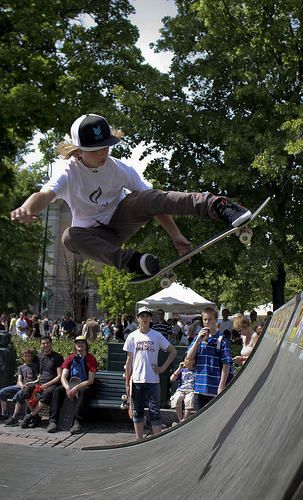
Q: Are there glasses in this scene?
A: No, there are no glasses.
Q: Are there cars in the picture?
A: No, there are no cars.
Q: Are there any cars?
A: No, there are no cars.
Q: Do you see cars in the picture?
A: No, there are no cars.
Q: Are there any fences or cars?
A: No, there are no cars or fences.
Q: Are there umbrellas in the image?
A: No, there are no umbrellas.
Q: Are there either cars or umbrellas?
A: No, there are no umbrellas or cars.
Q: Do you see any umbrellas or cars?
A: No, there are no umbrellas or cars.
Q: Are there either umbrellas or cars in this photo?
A: No, there are no umbrellas or cars.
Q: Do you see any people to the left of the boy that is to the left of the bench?
A: Yes, there are people to the left of the boy.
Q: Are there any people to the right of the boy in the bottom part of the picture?
A: No, the people are to the left of the boy.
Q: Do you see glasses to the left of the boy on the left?
A: No, there are people to the left of the boy.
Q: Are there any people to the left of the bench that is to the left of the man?
A: Yes, there are people to the left of the bench.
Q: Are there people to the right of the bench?
A: No, the people are to the left of the bench.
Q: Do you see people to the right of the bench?
A: No, the people are to the left of the bench.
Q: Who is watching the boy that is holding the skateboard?
A: The people are watching the boy.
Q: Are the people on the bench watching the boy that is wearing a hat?
A: Yes, the people are watching the boy.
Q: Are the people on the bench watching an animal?
A: No, the people are watching the boy.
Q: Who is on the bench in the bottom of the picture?
A: The people are on the bench.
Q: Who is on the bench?
A: The people are on the bench.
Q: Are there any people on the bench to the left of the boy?
A: Yes, there are people on the bench.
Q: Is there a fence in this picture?
A: No, there are no fences.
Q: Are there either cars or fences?
A: No, there are no fences or cars.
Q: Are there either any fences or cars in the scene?
A: No, there are no fences or cars.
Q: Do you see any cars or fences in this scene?
A: No, there are no fences or cars.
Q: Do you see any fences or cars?
A: No, there are no fences or cars.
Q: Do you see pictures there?
A: No, there are no pictures.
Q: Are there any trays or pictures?
A: No, there are no pictures or trays.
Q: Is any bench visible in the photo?
A: Yes, there is a bench.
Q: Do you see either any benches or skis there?
A: Yes, there is a bench.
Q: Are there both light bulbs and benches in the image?
A: No, there is a bench but no light bulbs.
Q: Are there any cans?
A: No, there are no cans.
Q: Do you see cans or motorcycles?
A: No, there are no cans or motorcycles.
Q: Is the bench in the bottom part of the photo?
A: Yes, the bench is in the bottom of the image.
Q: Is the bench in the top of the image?
A: No, the bench is in the bottom of the image.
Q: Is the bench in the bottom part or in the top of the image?
A: The bench is in the bottom of the image.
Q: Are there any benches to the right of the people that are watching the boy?
A: Yes, there is a bench to the right of the people.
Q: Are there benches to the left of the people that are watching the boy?
A: No, the bench is to the right of the people.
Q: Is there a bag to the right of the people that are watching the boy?
A: No, there is a bench to the right of the people.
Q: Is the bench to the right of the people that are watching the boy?
A: Yes, the bench is to the right of the people.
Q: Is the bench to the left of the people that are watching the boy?
A: No, the bench is to the right of the people.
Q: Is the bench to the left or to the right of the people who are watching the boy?
A: The bench is to the right of the people.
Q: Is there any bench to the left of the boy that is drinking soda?
A: Yes, there is a bench to the left of the boy.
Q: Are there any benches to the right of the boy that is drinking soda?
A: No, the bench is to the left of the boy.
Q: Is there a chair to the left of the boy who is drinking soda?
A: No, there is a bench to the left of the boy.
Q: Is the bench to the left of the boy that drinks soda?
A: Yes, the bench is to the left of the boy.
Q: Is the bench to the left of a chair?
A: No, the bench is to the left of the boy.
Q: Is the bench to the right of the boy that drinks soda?
A: No, the bench is to the left of the boy.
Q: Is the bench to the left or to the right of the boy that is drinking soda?
A: The bench is to the left of the boy.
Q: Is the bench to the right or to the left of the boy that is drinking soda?
A: The bench is to the left of the boy.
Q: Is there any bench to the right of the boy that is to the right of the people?
A: Yes, there is a bench to the right of the boy.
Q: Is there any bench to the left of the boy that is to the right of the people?
A: No, the bench is to the right of the boy.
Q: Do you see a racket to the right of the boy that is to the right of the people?
A: No, there is a bench to the right of the boy.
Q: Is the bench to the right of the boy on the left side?
A: Yes, the bench is to the right of the boy.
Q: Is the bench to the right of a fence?
A: No, the bench is to the right of the boy.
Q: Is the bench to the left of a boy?
A: No, the bench is to the right of a boy.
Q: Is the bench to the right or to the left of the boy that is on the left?
A: The bench is to the right of the boy.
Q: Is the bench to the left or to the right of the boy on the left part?
A: The bench is to the right of the boy.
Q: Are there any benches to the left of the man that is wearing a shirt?
A: Yes, there is a bench to the left of the man.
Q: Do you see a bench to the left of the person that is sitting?
A: Yes, there is a bench to the left of the man.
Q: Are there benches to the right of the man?
A: No, the bench is to the left of the man.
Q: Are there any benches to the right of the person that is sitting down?
A: No, the bench is to the left of the man.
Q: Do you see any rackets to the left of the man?
A: No, there is a bench to the left of the man.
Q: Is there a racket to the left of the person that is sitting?
A: No, there is a bench to the left of the man.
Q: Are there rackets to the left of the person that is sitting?
A: No, there is a bench to the left of the man.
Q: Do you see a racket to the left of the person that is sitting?
A: No, there is a bench to the left of the man.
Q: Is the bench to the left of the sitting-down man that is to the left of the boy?
A: Yes, the bench is to the left of the man.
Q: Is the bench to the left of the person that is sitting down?
A: Yes, the bench is to the left of the man.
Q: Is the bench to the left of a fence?
A: No, the bench is to the left of the man.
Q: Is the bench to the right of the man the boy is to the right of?
A: No, the bench is to the left of the man.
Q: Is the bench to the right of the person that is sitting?
A: No, the bench is to the left of the man.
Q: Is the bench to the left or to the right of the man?
A: The bench is to the left of the man.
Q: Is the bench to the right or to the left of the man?
A: The bench is to the left of the man.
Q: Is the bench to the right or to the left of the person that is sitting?
A: The bench is to the left of the man.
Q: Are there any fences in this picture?
A: No, there are no fences.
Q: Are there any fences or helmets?
A: No, there are no fences or helmets.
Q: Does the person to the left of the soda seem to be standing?
A: Yes, the person is standing.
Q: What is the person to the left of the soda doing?
A: The person is standing.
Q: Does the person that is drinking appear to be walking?
A: No, the person is standing.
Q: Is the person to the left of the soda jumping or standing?
A: The person is standing.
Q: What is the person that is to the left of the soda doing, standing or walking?
A: The person is standing.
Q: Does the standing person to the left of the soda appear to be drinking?
A: Yes, the person is drinking.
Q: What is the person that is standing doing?
A: The person is drinking.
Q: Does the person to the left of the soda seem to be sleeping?
A: No, the person is drinking.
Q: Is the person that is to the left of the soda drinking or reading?
A: The person is drinking.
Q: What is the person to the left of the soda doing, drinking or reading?
A: The person is drinking.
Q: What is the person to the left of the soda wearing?
A: The person is wearing a shirt.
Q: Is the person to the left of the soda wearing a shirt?
A: Yes, the person is wearing a shirt.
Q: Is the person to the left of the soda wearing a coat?
A: No, the person is wearing a shirt.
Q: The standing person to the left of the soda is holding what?
A: The person is holding the skateboard.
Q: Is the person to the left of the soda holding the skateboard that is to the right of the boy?
A: Yes, the person is holding the skateboard.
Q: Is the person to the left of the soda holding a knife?
A: No, the person is holding the skateboard.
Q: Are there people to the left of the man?
A: Yes, there is a person to the left of the man.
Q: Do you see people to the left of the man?
A: Yes, there is a person to the left of the man.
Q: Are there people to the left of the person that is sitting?
A: Yes, there is a person to the left of the man.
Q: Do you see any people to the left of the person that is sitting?
A: Yes, there is a person to the left of the man.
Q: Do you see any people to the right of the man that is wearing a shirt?
A: No, the person is to the left of the man.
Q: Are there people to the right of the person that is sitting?
A: No, the person is to the left of the man.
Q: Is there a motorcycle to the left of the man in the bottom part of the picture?
A: No, there is a person to the left of the man.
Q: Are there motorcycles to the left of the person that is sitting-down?
A: No, there is a person to the left of the man.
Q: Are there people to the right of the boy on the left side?
A: Yes, there is a person to the right of the boy.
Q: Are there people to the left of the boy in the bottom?
A: No, the person is to the right of the boy.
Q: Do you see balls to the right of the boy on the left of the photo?
A: No, there is a person to the right of the boy.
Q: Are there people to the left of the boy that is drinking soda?
A: Yes, there is a person to the left of the boy.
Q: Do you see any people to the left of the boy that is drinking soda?
A: Yes, there is a person to the left of the boy.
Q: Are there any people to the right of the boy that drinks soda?
A: No, the person is to the left of the boy.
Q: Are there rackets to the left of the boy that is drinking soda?
A: No, there is a person to the left of the boy.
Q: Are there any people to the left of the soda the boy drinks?
A: Yes, there is a person to the left of the soda.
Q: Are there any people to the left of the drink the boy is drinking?
A: Yes, there is a person to the left of the soda.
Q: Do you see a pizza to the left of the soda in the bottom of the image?
A: No, there is a person to the left of the soda.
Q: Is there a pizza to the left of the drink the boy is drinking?
A: No, there is a person to the left of the soda.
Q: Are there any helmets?
A: No, there are no helmets.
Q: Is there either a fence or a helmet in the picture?
A: No, there are no helmets or fences.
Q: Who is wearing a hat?
A: The boy is wearing a hat.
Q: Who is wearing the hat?
A: The boy is wearing a hat.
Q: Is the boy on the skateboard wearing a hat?
A: Yes, the boy is wearing a hat.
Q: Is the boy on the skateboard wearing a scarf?
A: No, the boy is wearing a hat.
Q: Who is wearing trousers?
A: The boy is wearing trousers.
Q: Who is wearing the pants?
A: The boy is wearing trousers.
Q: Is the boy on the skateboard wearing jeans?
A: No, the boy is wearing pants.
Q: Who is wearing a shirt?
A: The boy is wearing a shirt.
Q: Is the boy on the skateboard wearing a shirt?
A: Yes, the boy is wearing a shirt.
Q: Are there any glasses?
A: No, there are no glasses.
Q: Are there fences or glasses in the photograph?
A: No, there are no glasses or fences.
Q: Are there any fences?
A: No, there are no fences.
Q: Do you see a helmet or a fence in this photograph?
A: No, there are no fences or helmets.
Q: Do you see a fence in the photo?
A: No, there are no fences.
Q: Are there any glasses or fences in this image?
A: No, there are no fences or glasses.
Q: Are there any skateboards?
A: Yes, there is a skateboard.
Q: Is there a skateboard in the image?
A: Yes, there is a skateboard.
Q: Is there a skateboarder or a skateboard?
A: Yes, there is a skateboard.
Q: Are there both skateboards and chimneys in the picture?
A: No, there is a skateboard but no chimneys.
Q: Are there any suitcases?
A: No, there are no suitcases.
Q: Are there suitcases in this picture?
A: No, there are no suitcases.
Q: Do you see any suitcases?
A: No, there are no suitcases.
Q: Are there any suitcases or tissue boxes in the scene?
A: No, there are no suitcases or tissue boxes.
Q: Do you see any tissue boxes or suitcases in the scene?
A: No, there are no suitcases or tissue boxes.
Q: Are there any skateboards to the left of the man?
A: Yes, there is a skateboard to the left of the man.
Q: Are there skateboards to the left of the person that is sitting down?
A: Yes, there is a skateboard to the left of the man.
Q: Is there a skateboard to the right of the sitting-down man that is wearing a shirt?
A: No, the skateboard is to the left of the man.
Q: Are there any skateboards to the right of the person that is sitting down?
A: No, the skateboard is to the left of the man.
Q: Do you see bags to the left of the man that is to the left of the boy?
A: No, there is a skateboard to the left of the man.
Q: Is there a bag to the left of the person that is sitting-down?
A: No, there is a skateboard to the left of the man.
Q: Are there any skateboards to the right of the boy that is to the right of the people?
A: Yes, there is a skateboard to the right of the boy.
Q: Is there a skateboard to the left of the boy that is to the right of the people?
A: No, the skateboard is to the right of the boy.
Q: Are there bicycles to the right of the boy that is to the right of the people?
A: No, there is a skateboard to the right of the boy.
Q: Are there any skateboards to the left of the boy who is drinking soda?
A: Yes, there is a skateboard to the left of the boy.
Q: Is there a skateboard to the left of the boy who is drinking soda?
A: Yes, there is a skateboard to the left of the boy.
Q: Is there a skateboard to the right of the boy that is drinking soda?
A: No, the skateboard is to the left of the boy.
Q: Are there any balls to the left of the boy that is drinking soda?
A: No, there is a skateboard to the left of the boy.